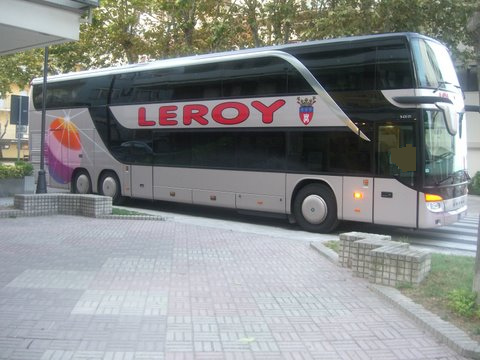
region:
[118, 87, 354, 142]
a sign on the side of a bus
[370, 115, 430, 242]
the front door of a bus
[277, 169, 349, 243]
a front wheel on a bus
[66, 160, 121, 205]
the two back wheels of a bus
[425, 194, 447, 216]
a headlight on a bus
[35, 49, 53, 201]
a lamppost next to a bus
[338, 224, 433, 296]
stacked decorative bricks next to a sidewalk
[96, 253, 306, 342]
a sidewalk made of decorative bricks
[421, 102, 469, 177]
the front windshield of a bus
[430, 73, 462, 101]
windshield wipers on the front windshield of a bus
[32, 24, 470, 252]
this is a bus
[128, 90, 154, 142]
a letter on a bus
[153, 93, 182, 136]
a letter on a bus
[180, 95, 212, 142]
a letter on a bus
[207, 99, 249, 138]
a letter on a bus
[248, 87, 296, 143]
a letter on a bus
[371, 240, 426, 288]
a block of bricks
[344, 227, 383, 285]
a block of bricks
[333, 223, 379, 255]
a block of bricks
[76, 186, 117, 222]
a block of bricks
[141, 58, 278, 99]
tinted windows on silver bus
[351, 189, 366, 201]
yellow amber light on silver bus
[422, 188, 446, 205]
yellow turn signal on side of bus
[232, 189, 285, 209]
luggage compartment on side of grey bus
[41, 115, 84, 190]
multi color ball on silver bus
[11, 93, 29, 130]
black window on beige building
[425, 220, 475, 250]
white crosswalk line on street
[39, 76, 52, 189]
black street pole beside of bus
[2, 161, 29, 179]
green shrubs behind grey bus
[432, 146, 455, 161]
steering wheel inside cockpit of bus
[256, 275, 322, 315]
White brick side walk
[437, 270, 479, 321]
Green plate near side walk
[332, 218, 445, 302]
Block structure near side walk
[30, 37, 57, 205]
Metal light pole near bus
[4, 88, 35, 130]
Road sign near bus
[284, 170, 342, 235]
Right front wheel of bus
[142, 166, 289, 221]
luggage compartment of bus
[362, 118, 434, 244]
Front door of bus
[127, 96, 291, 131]
Name Leroy on side of bus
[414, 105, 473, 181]
Front windshield of bus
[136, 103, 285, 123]
large red letters on the bus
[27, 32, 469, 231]
silver and black passenger bus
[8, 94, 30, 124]
back of the street sign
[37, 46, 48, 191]
street light post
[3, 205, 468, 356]
brick pattern sidewalk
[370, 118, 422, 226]
passenger entrance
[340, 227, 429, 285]
concrete seating area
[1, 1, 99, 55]
edge of building roof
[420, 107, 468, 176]
large windshield on the bus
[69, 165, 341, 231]
three large bus tires